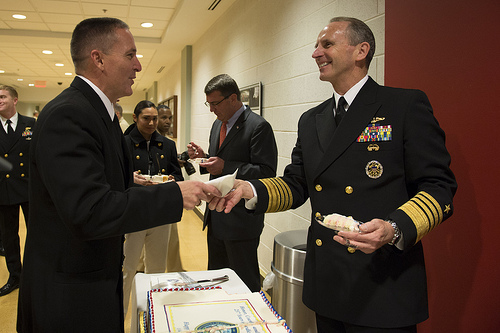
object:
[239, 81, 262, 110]
picture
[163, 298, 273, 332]
cake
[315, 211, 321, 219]
button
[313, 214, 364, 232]
plate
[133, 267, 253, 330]
cake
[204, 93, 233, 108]
glasses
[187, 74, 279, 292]
man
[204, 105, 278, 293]
suit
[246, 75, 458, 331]
uniform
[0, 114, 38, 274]
uniform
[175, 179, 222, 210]
hands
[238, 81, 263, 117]
frame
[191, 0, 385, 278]
wall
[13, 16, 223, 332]
man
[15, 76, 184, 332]
black suit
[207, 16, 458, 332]
man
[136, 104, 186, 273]
man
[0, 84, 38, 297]
man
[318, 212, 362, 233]
cake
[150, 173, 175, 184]
cake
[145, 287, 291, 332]
cake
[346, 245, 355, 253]
button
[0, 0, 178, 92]
tiled ceiling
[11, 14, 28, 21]
white lights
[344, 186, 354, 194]
button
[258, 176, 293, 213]
stripes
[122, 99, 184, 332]
lady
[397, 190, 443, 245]
gold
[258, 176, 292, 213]
gold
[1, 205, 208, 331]
floor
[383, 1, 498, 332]
wall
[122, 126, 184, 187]
jacket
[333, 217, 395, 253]
hand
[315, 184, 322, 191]
button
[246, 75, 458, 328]
jacket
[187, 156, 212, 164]
plates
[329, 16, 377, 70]
hair